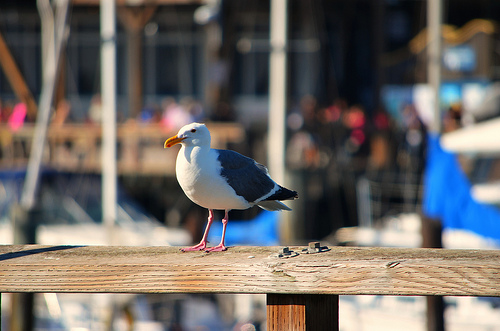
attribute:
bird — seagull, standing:
[145, 115, 307, 259]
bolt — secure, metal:
[268, 241, 299, 261]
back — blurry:
[4, 6, 494, 245]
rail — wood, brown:
[3, 243, 492, 326]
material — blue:
[422, 135, 498, 240]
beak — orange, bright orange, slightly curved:
[152, 132, 190, 151]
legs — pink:
[175, 203, 241, 254]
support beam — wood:
[3, 117, 252, 176]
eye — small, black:
[189, 128, 200, 136]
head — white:
[159, 116, 214, 157]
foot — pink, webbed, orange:
[179, 237, 210, 254]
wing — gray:
[217, 152, 302, 207]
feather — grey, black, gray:
[255, 163, 272, 176]